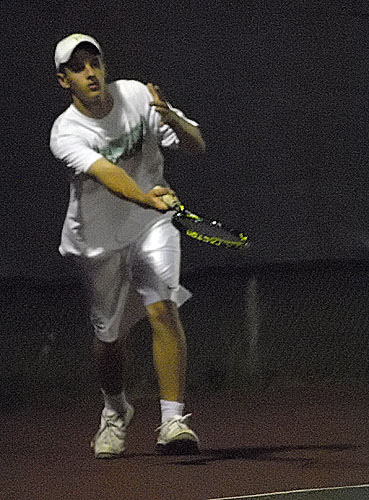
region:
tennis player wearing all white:
[37, 29, 242, 459]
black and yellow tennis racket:
[158, 185, 248, 257]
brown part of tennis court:
[13, 381, 367, 482]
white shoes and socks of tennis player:
[85, 384, 200, 453]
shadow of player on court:
[169, 427, 368, 469]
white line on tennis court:
[227, 473, 363, 498]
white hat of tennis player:
[46, 29, 103, 63]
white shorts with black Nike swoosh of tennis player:
[74, 226, 192, 327]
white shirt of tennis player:
[50, 84, 187, 256]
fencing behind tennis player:
[8, 264, 353, 371]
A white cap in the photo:
[51, 32, 100, 64]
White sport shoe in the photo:
[158, 416, 201, 446]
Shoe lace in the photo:
[160, 413, 192, 427]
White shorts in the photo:
[90, 260, 176, 337]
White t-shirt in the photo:
[48, 106, 177, 254]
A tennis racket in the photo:
[168, 203, 251, 252]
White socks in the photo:
[154, 397, 186, 420]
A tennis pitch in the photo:
[239, 421, 359, 478]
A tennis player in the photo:
[46, 36, 222, 461]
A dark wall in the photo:
[224, 70, 365, 195]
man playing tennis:
[44, 17, 259, 455]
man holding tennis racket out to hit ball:
[60, 133, 258, 255]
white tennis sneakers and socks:
[80, 379, 256, 468]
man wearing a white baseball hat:
[52, 25, 111, 98]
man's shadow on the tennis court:
[153, 431, 352, 480]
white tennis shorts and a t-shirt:
[63, 76, 203, 352]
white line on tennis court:
[257, 483, 365, 497]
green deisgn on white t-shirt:
[68, 111, 175, 185]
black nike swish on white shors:
[160, 279, 191, 296]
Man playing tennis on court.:
[48, 29, 254, 455]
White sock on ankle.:
[153, 392, 201, 455]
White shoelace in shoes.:
[156, 410, 210, 453]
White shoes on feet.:
[82, 389, 202, 467]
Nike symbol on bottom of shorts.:
[160, 277, 181, 300]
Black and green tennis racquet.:
[157, 188, 251, 256]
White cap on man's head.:
[47, 32, 113, 108]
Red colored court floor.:
[1, 404, 367, 496]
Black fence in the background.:
[6, 256, 366, 405]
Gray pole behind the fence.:
[234, 264, 277, 388]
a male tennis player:
[40, 24, 294, 447]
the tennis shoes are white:
[76, 348, 215, 478]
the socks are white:
[59, 343, 217, 462]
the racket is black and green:
[160, 176, 239, 308]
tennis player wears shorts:
[53, 198, 284, 383]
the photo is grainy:
[10, 15, 339, 442]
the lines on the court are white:
[294, 426, 354, 493]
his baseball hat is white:
[39, 37, 183, 178]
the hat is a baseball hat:
[32, 1, 133, 157]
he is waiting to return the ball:
[43, 28, 265, 295]